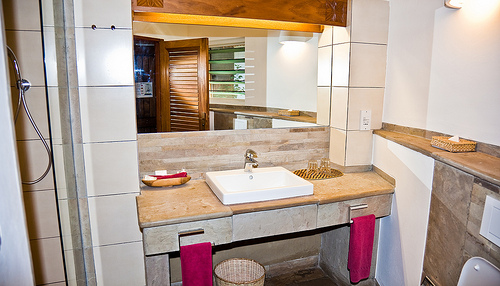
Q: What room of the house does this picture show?
A: The bathroom.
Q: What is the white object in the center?
A: Sink.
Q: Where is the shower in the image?
A: The left.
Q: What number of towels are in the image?
A: Two.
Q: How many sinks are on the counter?
A: One.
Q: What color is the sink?
A: White.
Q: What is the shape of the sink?
A: Square.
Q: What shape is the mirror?
A: Rectangle.